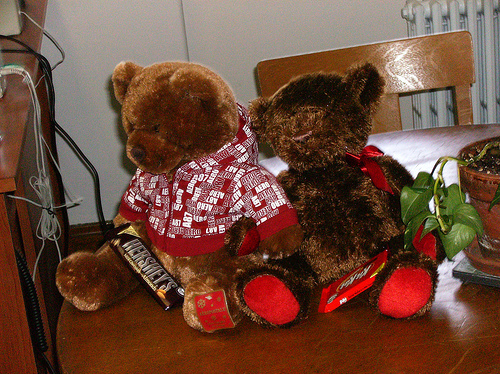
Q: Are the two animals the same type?
A: Yes, all the animals are bears.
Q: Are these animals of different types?
A: No, all the animals are bears.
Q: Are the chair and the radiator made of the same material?
A: No, the chair is made of wood and the radiator is made of metal.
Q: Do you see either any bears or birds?
A: Yes, there is a bear.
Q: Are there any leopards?
A: No, there are no leopards.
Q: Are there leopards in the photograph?
A: No, there are no leopards.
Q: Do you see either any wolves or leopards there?
A: No, there are no leopards or wolves.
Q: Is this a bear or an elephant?
A: This is a bear.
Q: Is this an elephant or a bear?
A: This is a bear.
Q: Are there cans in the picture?
A: No, there are no cans.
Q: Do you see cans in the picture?
A: No, there are no cans.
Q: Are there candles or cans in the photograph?
A: No, there are no cans or candles.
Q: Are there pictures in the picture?
A: No, there are no pictures.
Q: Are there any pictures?
A: No, there are no pictures.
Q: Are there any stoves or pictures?
A: No, there are no pictures or stoves.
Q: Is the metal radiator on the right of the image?
A: Yes, the radiator is on the right of the image.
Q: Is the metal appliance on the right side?
A: Yes, the radiator is on the right of the image.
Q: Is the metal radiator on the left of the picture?
A: No, the radiator is on the right of the image.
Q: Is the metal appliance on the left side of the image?
A: No, the radiator is on the right of the image.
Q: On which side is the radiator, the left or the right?
A: The radiator is on the right of the image.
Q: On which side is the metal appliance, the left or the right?
A: The radiator is on the right of the image.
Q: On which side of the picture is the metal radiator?
A: The radiator is on the right of the image.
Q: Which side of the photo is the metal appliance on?
A: The radiator is on the right of the image.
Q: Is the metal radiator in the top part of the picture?
A: Yes, the radiator is in the top of the image.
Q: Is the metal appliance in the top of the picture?
A: Yes, the radiator is in the top of the image.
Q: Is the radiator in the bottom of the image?
A: No, the radiator is in the top of the image.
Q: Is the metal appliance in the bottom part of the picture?
A: No, the radiator is in the top of the image.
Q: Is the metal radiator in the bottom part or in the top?
A: The radiator is in the top of the image.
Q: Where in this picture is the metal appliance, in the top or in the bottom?
A: The radiator is in the top of the image.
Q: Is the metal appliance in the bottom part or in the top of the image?
A: The radiator is in the top of the image.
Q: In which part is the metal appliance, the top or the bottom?
A: The radiator is in the top of the image.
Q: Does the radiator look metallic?
A: Yes, the radiator is metallic.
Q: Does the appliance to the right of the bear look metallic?
A: Yes, the radiator is metallic.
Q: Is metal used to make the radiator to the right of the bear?
A: Yes, the radiator is made of metal.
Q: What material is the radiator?
A: The radiator is made of metal.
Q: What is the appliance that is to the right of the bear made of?
A: The radiator is made of metal.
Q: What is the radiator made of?
A: The radiator is made of metal.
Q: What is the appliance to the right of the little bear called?
A: The appliance is a radiator.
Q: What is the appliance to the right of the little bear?
A: The appliance is a radiator.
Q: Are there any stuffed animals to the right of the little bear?
A: No, there is a radiator to the right of the bear.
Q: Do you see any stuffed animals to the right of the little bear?
A: No, there is a radiator to the right of the bear.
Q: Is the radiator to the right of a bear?
A: Yes, the radiator is to the right of a bear.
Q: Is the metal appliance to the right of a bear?
A: Yes, the radiator is to the right of a bear.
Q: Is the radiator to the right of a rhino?
A: No, the radiator is to the right of a bear.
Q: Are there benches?
A: No, there are no benches.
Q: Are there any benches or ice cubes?
A: No, there are no benches or ice cubes.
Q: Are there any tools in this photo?
A: No, there are no tools.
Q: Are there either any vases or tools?
A: No, there are no tools or vases.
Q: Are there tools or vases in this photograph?
A: No, there are no tools or vases.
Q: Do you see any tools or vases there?
A: No, there are no tools or vases.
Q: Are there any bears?
A: Yes, there is a bear.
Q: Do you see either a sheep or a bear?
A: Yes, there is a bear.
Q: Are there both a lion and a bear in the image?
A: No, there is a bear but no lions.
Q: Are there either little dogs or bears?
A: Yes, there is a little bear.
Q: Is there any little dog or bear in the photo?
A: Yes, there is a little bear.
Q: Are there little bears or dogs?
A: Yes, there is a little bear.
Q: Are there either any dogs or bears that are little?
A: Yes, the bear is little.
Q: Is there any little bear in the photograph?
A: Yes, there is a little bear.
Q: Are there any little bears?
A: Yes, there is a little bear.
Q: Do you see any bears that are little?
A: Yes, there is a bear that is little.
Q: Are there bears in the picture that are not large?
A: Yes, there is a little bear.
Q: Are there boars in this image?
A: No, there are no boars.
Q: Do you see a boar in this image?
A: No, there are no boars.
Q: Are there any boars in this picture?
A: No, there are no boars.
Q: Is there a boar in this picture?
A: No, there are no boars.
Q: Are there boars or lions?
A: No, there are no boars or lions.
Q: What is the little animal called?
A: The animal is a bear.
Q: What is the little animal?
A: The animal is a bear.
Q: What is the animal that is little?
A: The animal is a bear.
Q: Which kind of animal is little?
A: The animal is a bear.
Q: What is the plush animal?
A: The animal is a bear.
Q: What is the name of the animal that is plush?
A: The animal is a bear.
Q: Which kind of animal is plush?
A: The animal is a bear.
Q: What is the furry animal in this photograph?
A: The animal is a bear.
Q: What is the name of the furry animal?
A: The animal is a bear.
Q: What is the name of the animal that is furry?
A: The animal is a bear.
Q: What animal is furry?
A: The animal is a bear.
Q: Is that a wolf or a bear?
A: That is a bear.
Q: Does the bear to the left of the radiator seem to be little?
A: Yes, the bear is little.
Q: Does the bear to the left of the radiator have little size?
A: Yes, the bear is little.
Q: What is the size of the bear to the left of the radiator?
A: The bear is little.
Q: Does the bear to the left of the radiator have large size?
A: No, the bear is little.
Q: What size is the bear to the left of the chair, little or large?
A: The bear is little.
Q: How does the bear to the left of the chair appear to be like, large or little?
A: The bear is little.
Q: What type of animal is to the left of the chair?
A: The animal is a bear.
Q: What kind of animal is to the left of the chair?
A: The animal is a bear.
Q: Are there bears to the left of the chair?
A: Yes, there is a bear to the left of the chair.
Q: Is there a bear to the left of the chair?
A: Yes, there is a bear to the left of the chair.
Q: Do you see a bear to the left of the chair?
A: Yes, there is a bear to the left of the chair.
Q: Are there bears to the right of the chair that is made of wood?
A: No, the bear is to the left of the chair.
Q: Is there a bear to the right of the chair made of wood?
A: No, the bear is to the left of the chair.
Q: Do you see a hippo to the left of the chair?
A: No, there is a bear to the left of the chair.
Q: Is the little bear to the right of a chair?
A: No, the bear is to the left of a chair.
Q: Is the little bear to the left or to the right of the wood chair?
A: The bear is to the left of the chair.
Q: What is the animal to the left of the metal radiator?
A: The animal is a bear.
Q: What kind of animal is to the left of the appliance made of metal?
A: The animal is a bear.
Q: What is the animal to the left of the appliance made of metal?
A: The animal is a bear.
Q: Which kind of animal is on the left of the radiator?
A: The animal is a bear.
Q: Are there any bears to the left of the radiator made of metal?
A: Yes, there is a bear to the left of the radiator.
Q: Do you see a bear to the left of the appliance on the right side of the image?
A: Yes, there is a bear to the left of the radiator.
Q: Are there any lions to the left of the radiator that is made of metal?
A: No, there is a bear to the left of the radiator.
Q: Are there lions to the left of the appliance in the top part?
A: No, there is a bear to the left of the radiator.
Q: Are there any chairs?
A: Yes, there is a chair.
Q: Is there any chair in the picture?
A: Yes, there is a chair.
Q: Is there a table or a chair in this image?
A: Yes, there is a chair.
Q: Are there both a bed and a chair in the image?
A: No, there is a chair but no beds.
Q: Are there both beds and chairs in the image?
A: No, there is a chair but no beds.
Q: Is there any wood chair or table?
A: Yes, there is a wood chair.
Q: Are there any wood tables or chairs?
A: Yes, there is a wood chair.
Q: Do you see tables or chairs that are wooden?
A: Yes, the chair is wooden.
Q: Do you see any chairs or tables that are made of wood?
A: Yes, the chair is made of wood.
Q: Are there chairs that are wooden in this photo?
A: Yes, there is a wood chair.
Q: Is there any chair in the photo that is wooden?
A: Yes, there is a chair that is wooden.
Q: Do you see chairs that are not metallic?
A: Yes, there is a wooden chair.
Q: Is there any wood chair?
A: Yes, there is a chair that is made of wood.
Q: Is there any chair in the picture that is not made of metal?
A: Yes, there is a chair that is made of wood.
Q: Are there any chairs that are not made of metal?
A: Yes, there is a chair that is made of wood.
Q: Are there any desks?
A: No, there are no desks.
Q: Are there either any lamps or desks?
A: No, there are no desks or lamps.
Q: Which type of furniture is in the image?
A: The furniture is a chair.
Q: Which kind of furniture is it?
A: The piece of furniture is a chair.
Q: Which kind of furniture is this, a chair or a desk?
A: This is a chair.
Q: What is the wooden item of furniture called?
A: The piece of furniture is a chair.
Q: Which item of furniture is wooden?
A: The piece of furniture is a chair.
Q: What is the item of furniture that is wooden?
A: The piece of furniture is a chair.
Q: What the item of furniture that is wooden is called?
A: The piece of furniture is a chair.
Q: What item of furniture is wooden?
A: The piece of furniture is a chair.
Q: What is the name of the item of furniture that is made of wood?
A: The piece of furniture is a chair.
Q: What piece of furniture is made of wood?
A: The piece of furniture is a chair.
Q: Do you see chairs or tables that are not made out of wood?
A: No, there is a chair but it is made of wood.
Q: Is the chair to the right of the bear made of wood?
A: Yes, the chair is made of wood.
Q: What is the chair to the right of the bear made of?
A: The chair is made of wood.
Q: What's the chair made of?
A: The chair is made of wood.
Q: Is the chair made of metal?
A: No, the chair is made of wood.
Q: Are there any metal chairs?
A: No, there is a chair but it is made of wood.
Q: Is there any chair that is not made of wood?
A: No, there is a chair but it is made of wood.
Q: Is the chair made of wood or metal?
A: The chair is made of wood.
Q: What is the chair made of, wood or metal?
A: The chair is made of wood.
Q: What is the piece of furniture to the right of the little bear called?
A: The piece of furniture is a chair.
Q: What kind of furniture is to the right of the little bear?
A: The piece of furniture is a chair.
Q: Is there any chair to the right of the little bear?
A: Yes, there is a chair to the right of the bear.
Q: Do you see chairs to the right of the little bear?
A: Yes, there is a chair to the right of the bear.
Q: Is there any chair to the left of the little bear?
A: No, the chair is to the right of the bear.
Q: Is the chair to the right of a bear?
A: Yes, the chair is to the right of a bear.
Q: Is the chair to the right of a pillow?
A: No, the chair is to the right of a bear.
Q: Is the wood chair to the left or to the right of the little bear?
A: The chair is to the right of the bear.